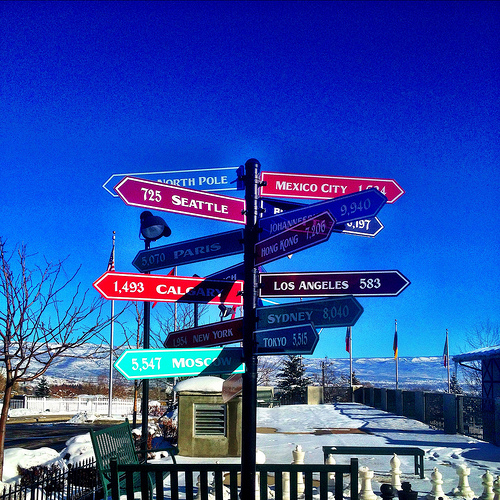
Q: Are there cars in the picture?
A: No, there are no cars.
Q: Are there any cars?
A: No, there are no cars.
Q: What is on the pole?
A: The sign is on the pole.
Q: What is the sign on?
A: The sign is on the pole.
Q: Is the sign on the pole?
A: Yes, the sign is on the pole.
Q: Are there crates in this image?
A: No, there are no crates.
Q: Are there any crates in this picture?
A: No, there are no crates.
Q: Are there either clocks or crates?
A: No, there are no crates or clocks.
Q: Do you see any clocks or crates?
A: No, there are no crates or clocks.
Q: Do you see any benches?
A: Yes, there is a bench.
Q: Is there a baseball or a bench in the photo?
A: Yes, there is a bench.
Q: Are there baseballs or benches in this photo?
A: Yes, there is a bench.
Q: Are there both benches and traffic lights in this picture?
A: No, there is a bench but no traffic lights.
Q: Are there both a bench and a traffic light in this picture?
A: No, there is a bench but no traffic lights.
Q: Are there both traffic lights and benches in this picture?
A: No, there is a bench but no traffic lights.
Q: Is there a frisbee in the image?
A: No, there are no frisbees.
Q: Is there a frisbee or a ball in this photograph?
A: No, there are no frisbees or balls.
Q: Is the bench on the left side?
A: Yes, the bench is on the left of the image.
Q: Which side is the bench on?
A: The bench is on the left of the image.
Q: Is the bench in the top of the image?
A: No, the bench is in the bottom of the image.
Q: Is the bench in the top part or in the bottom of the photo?
A: The bench is in the bottom of the image.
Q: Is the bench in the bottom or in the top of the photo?
A: The bench is in the bottom of the image.